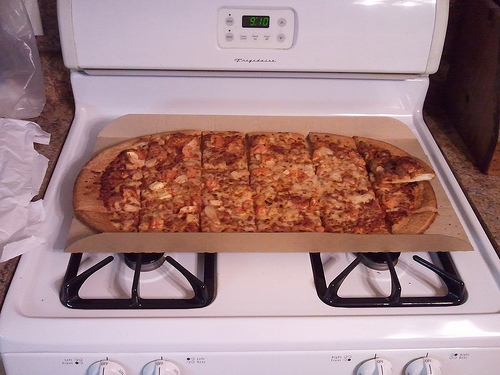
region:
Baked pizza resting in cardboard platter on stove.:
[63, 113, 475, 251]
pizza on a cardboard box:
[40, 98, 469, 278]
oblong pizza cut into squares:
[68, 121, 450, 250]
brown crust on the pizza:
[62, 133, 122, 233]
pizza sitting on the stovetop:
[51, 95, 491, 316]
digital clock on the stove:
[236, 13, 273, 34]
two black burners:
[53, 241, 473, 318]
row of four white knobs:
[82, 356, 446, 374]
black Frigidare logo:
[229, 53, 285, 70]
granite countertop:
[437, 126, 499, 244]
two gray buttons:
[221, 11, 240, 46]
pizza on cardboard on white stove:
[4, 5, 498, 370]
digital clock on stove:
[240, 12, 272, 32]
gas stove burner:
[309, 251, 472, 308]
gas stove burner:
[61, 251, 220, 313]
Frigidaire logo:
[232, 54, 277, 65]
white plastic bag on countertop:
[0, 114, 54, 265]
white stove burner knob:
[400, 355, 441, 371]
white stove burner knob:
[350, 353, 395, 373]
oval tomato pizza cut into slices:
[70, 125, 440, 240]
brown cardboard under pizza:
[69, 109, 480, 256]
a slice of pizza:
[379, 180, 432, 236]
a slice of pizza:
[357, 127, 436, 184]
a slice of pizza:
[325, 193, 380, 242]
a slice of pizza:
[307, 127, 370, 192]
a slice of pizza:
[260, 186, 320, 233]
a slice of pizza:
[254, 124, 321, 188]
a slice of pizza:
[202, 185, 259, 240]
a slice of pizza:
[202, 131, 252, 181]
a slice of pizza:
[144, 135, 208, 186]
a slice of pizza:
[136, 175, 203, 228]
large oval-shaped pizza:
[71, 113, 445, 258]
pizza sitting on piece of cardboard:
[61, 106, 482, 268]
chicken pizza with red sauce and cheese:
[65, 105, 453, 267]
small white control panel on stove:
[211, 5, 297, 50]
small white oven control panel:
[210, 0, 306, 52]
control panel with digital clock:
[211, 1, 302, 51]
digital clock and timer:
[240, 8, 274, 35]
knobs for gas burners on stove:
[71, 350, 458, 373]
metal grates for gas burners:
[52, 236, 474, 316]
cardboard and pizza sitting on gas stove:
[55, 103, 476, 277]